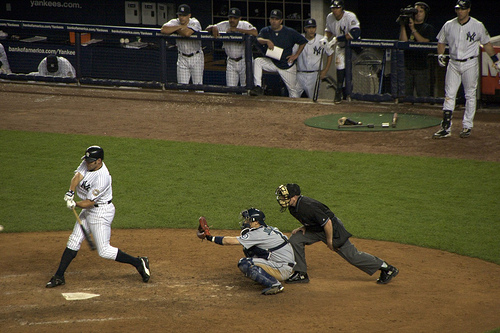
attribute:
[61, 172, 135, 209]
jersey — is white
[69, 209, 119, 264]
pants — are white, are striped 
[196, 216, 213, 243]
mitt — brown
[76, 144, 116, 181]
mask — brown, gold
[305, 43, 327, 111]
bat — black, shiny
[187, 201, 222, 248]
glove — brown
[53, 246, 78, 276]
sock — tall, black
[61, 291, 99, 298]
plate — is white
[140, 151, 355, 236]
turf — green, artificial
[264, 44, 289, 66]
paper — white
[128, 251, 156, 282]
shoe — is black, is white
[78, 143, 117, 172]
helmet — is black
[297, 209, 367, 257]
clothing — dark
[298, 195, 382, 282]
dressed — black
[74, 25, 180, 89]
railing — black